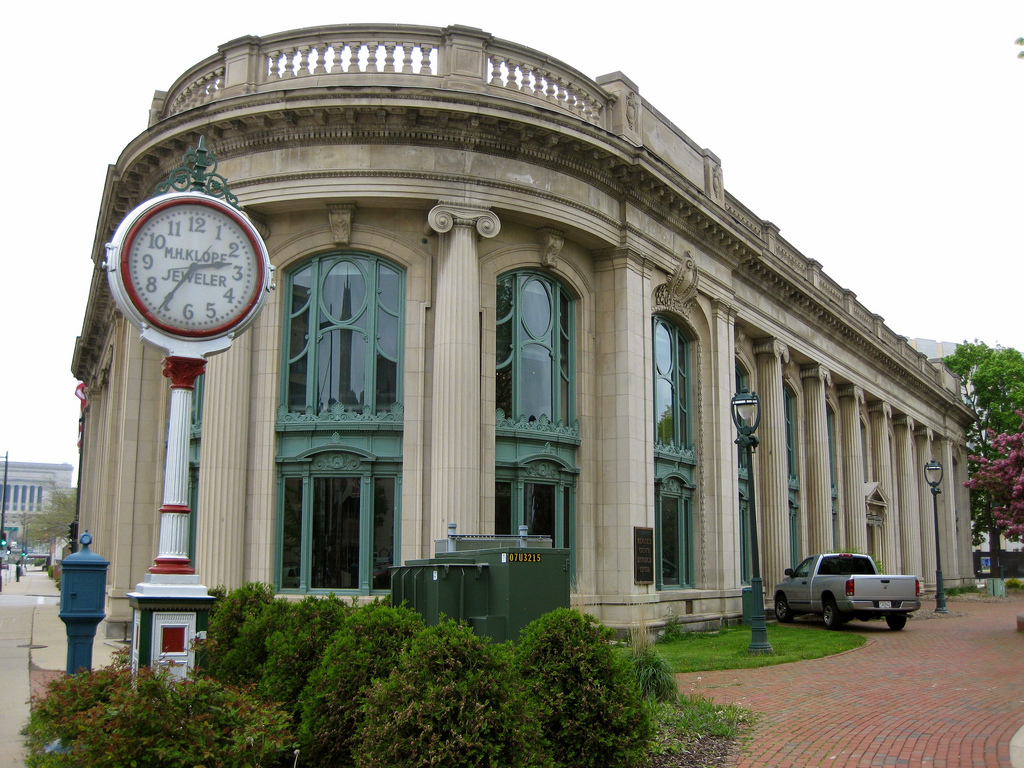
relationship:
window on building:
[282, 250, 406, 419] [56, 7, 1020, 641]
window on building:
[492, 452, 562, 543] [56, 7, 1020, 641]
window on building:
[495, 261, 586, 447] [68, 5, 965, 604]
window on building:
[659, 315, 706, 469] [56, 7, 1020, 641]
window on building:
[652, 469, 704, 591] [56, 7, 1020, 641]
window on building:
[732, 497, 769, 599] [56, 7, 1020, 641]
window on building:
[786, 399, 810, 505] [519, 447, 787, 633]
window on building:
[780, 520, 809, 546] [570, 416, 972, 661]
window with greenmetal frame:
[282, 250, 406, 419] [307, 282, 372, 397]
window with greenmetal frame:
[495, 261, 586, 447] [512, 302, 577, 398]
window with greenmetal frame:
[492, 453, 561, 544] [506, 479, 565, 523]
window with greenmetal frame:
[659, 315, 707, 469] [663, 365, 683, 417]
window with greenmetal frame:
[653, 438, 712, 626] [670, 494, 697, 553]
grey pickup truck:
[851, 561, 903, 592] [767, 513, 962, 626]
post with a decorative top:
[41, 499, 145, 768] [65, 537, 126, 617]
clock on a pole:
[120, 193, 267, 336] [76, 209, 344, 678]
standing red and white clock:
[97, 172, 273, 657] [136, 213, 253, 352]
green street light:
[722, 369, 802, 650] [732, 367, 774, 534]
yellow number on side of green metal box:
[506, 540, 548, 567] [357, 496, 606, 721]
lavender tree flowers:
[925, 451, 1021, 581] [940, 457, 1021, 488]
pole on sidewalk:
[50, 520, 113, 735] [9, 619, 79, 768]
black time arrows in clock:
[160, 259, 195, 309] [138, 205, 253, 387]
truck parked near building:
[771, 552, 923, 624] [56, 7, 1020, 641]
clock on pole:
[120, 193, 267, 336] [127, 355, 218, 675]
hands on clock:
[157, 234, 233, 310] [133, 202, 261, 332]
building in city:
[56, 7, 1020, 641] [2, 3, 1022, 764]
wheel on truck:
[818, 593, 844, 632] [773, 549, 923, 629]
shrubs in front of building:
[15, 577, 688, 765] [56, 7, 1020, 641]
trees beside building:
[943, 340, 1021, 578] [56, 7, 1020, 641]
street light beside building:
[917, 450, 952, 619] [56, 7, 1020, 641]